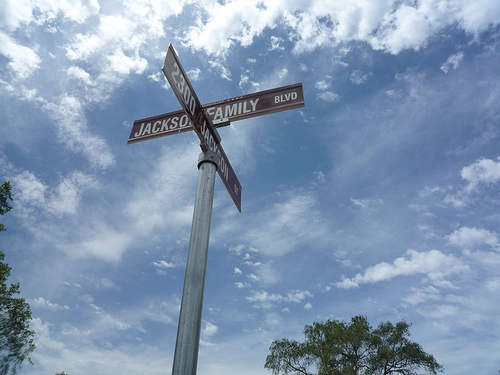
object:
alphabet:
[134, 123, 145, 138]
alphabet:
[142, 123, 151, 136]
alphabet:
[151, 120, 161, 134]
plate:
[160, 43, 244, 213]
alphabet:
[238, 102, 243, 115]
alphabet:
[160, 117, 171, 131]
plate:
[125, 82, 305, 147]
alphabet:
[224, 103, 238, 117]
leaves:
[264, 314, 447, 374]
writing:
[274, 91, 299, 104]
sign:
[161, 42, 305, 213]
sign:
[126, 81, 305, 145]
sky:
[0, 0, 499, 171]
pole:
[170, 160, 220, 375]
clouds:
[0, 0, 150, 67]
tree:
[264, 311, 447, 375]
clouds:
[180, 0, 261, 45]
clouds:
[24, 192, 122, 266]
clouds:
[360, 207, 472, 295]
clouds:
[343, 21, 413, 58]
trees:
[0, 178, 37, 375]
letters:
[206, 106, 216, 116]